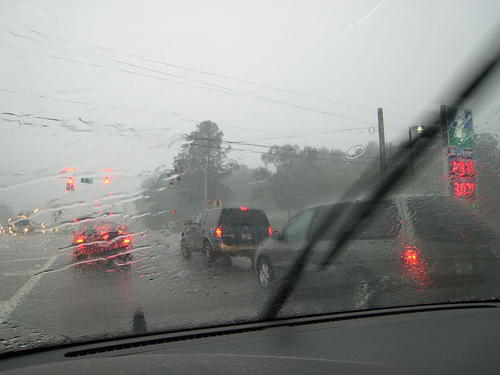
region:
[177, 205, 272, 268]
a dark colored SUV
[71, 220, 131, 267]
a car with tail lights on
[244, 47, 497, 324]
the blur of a windshield wiper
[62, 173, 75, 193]
a stop light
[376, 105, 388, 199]
a skinny pole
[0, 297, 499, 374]
the dashboard of a car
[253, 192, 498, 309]
a dark grey SUV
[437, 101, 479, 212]
a gasoline advertising sign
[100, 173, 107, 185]
a lit stop light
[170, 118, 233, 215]
a tall tree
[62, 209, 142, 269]
tail lights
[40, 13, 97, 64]
white clouds in blue sky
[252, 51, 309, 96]
white clouds in blue sky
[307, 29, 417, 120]
white clouds in blue sky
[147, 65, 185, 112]
white clouds in blue sky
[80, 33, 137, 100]
white clouds in blue sky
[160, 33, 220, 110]
white clouds in blue sky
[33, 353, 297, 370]
Yellow and green banana in the box.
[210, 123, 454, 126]
Yellow and green banana in the box.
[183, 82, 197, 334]
Yellow and green banana in the box.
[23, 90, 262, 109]
Yellow and green banana in the box.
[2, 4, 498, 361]
an extremely wet windshield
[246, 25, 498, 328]
a windshield wiper blade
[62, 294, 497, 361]
air vents on the inside front of a vehicle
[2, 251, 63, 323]
white lines drawn on the pavement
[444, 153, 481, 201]
an overhead sign with prices advertised in brightly lit red numbers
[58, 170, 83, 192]
an overhead traffic light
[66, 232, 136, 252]
the bright red tail lights of a vehicle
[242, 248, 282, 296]
the left front tire of a gray vehicle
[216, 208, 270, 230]
the rear window of a dark colored vehicle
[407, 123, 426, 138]
an illuminated street light high up on a pole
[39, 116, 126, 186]
a red traffic light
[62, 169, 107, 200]
a red traffic light in the air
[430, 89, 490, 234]
a gas station sign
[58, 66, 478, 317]
cars on the wet road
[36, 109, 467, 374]
cars on the road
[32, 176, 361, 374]
cars on the street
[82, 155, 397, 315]
cars with brake lights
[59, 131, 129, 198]
a sign in between traffic lights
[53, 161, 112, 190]
street sign on traffic light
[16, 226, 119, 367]
a white lines on the road